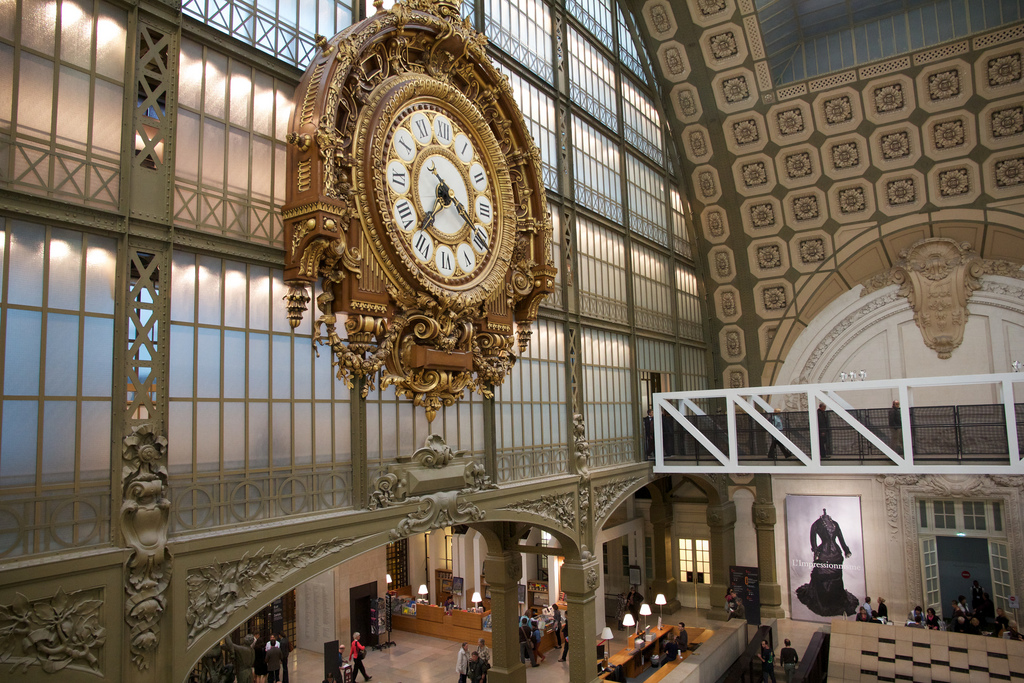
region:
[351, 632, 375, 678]
A person is walking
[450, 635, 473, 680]
A person is walking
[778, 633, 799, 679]
A person is walking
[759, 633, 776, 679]
A person is walking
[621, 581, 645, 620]
A person is walking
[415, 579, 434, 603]
A lamp is standing on the desk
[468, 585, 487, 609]
A lamp is standing on the desk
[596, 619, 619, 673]
A lamp is standing on the desk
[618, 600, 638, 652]
A lamp is standing on the desk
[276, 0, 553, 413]
the clock is fancy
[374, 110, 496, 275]
the circles are white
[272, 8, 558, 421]
the clock is gold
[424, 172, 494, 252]
hand of the clock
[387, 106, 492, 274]
numbers on the clock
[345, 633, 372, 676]
a person is walking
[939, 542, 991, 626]
entrance in the building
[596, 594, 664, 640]
a row of lamps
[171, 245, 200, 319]
glass panel is clear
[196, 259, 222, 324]
glass panel is clear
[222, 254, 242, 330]
glass panel is clear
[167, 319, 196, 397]
glass panel is clear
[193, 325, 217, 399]
glass panel is clear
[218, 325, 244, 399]
glass panel is clear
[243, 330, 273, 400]
glass panel is clear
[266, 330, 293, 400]
glass panel is clear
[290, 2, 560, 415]
clock is large and decorative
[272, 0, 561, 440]
clock is golden colored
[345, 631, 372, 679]
woman wearing a red shirt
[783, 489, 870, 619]
advertisement is large and for clothing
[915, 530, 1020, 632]
two doors are opened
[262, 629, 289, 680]
person walking on the tile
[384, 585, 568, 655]
reception desk is light brown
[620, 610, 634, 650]
small lamp is illuminated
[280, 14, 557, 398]
the very large gold black and white clock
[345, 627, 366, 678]
the person walking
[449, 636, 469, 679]
the person standing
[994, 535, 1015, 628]
the open white door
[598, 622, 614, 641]
the white lampshade backlit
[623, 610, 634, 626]
the white lamp shade backlit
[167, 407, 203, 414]
this picture is taken outdoorspicture is taken outdoors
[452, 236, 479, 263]
a number on the clock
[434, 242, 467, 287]
a number on the clock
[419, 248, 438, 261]
a number on the clock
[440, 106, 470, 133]
a number on the clock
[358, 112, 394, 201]
a number on the clock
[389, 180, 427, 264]
a number on the clock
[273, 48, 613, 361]
a large clock on the wall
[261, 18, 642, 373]
a golden clock on the wall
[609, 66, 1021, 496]
designs on the ceiling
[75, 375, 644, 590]
designs on the wall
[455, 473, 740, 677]
pillars in the building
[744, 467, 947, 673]
a dress on the wall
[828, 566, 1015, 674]
people on the floor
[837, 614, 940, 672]
tiles on the floor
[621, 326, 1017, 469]
a walkway in the building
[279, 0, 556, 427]
the large clock has a gold decorative frame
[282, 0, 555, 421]
the decorative clock is very large